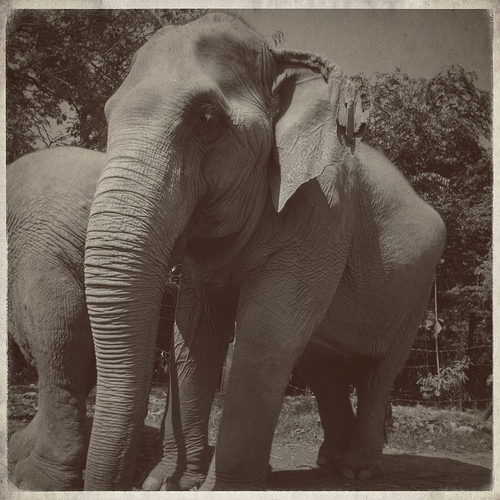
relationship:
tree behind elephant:
[7, 7, 203, 147] [77, 12, 452, 494]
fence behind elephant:
[159, 274, 496, 407] [77, 12, 452, 494]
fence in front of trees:
[159, 274, 496, 407] [5, 9, 498, 402]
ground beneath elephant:
[12, 379, 493, 492] [77, 12, 452, 494]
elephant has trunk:
[77, 12, 452, 494] [79, 129, 207, 495]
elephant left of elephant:
[3, 145, 105, 489] [77, 12, 452, 494]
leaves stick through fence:
[419, 357, 473, 407] [159, 274, 496, 407]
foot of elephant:
[315, 435, 347, 472] [77, 12, 452, 494]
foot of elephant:
[337, 440, 386, 483] [77, 12, 452, 494]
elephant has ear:
[77, 12, 452, 494] [274, 46, 374, 212]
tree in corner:
[7, 7, 203, 147] [8, 11, 109, 137]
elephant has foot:
[77, 12, 452, 494] [337, 440, 386, 483]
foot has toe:
[337, 440, 386, 483] [341, 465, 355, 483]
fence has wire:
[159, 274, 496, 407] [411, 343, 495, 355]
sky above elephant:
[233, 8, 493, 82] [77, 12, 452, 494]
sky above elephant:
[233, 8, 493, 82] [3, 145, 105, 489]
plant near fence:
[419, 357, 473, 407] [159, 274, 496, 407]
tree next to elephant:
[350, 60, 489, 346] [77, 12, 452, 494]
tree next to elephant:
[7, 7, 203, 147] [77, 12, 452, 494]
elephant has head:
[77, 12, 452, 494] [76, 10, 362, 489]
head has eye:
[76, 10, 362, 489] [192, 99, 230, 140]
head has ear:
[76, 10, 362, 489] [274, 46, 374, 212]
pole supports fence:
[431, 271, 444, 375] [159, 274, 496, 407]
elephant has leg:
[77, 12, 452, 494] [144, 275, 219, 493]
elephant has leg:
[77, 12, 452, 494] [197, 271, 338, 491]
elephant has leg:
[77, 12, 452, 494] [295, 354, 355, 470]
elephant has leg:
[77, 12, 452, 494] [340, 372, 395, 484]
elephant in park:
[77, 12, 452, 494] [1, 255, 491, 490]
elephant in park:
[3, 145, 105, 489] [1, 255, 491, 490]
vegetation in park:
[8, 381, 496, 457] [1, 255, 491, 490]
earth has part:
[12, 379, 493, 492] [389, 449, 484, 487]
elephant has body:
[77, 12, 452, 494] [268, 135, 449, 372]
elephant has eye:
[77, 12, 452, 494] [192, 99, 230, 140]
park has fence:
[1, 255, 491, 490] [159, 274, 496, 407]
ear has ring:
[274, 46, 374, 212] [345, 99, 359, 148]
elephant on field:
[77, 12, 452, 494] [12, 379, 493, 492]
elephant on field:
[3, 145, 105, 489] [12, 379, 493, 492]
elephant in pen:
[77, 12, 452, 494] [1, 255, 491, 490]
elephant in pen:
[3, 145, 105, 489] [1, 255, 491, 490]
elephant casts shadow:
[77, 12, 452, 494] [267, 450, 494, 489]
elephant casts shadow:
[3, 145, 105, 489] [82, 414, 164, 491]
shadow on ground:
[267, 450, 494, 489] [12, 379, 493, 492]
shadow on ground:
[82, 414, 164, 491] [12, 379, 493, 492]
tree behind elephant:
[7, 7, 203, 147] [3, 145, 105, 489]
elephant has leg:
[3, 145, 105, 489] [12, 258, 85, 490]